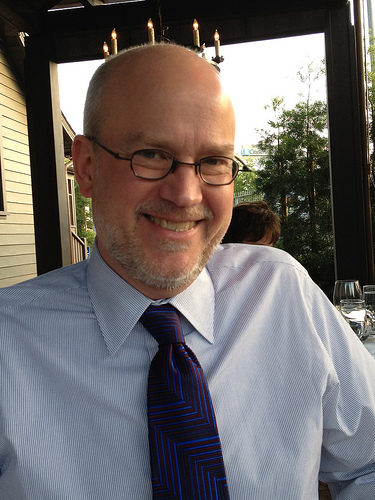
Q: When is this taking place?
A: Daytime.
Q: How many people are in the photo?
A: Two.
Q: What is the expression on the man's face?
A: Smile.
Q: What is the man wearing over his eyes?
A: Eyeglasses.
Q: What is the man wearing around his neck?
A: Tie.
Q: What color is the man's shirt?
A: Blue.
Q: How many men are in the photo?
A: One.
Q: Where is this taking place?
A: On a porch.